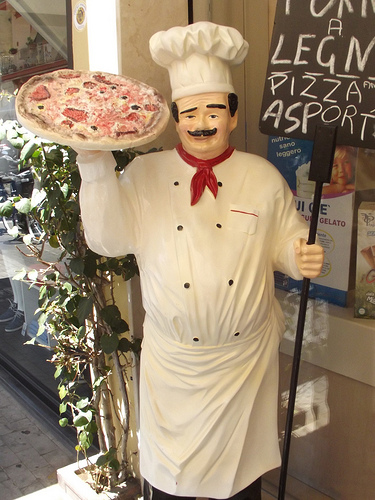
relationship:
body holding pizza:
[70, 19, 325, 499] [14, 69, 171, 152]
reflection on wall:
[283, 290, 332, 439] [0, 0, 373, 499]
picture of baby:
[268, 133, 354, 305] [320, 147, 356, 200]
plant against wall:
[0, 120, 133, 483] [0, 0, 373, 499]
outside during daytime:
[1, 0, 373, 499] [1, 1, 374, 500]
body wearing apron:
[70, 19, 325, 499] [138, 321, 282, 495]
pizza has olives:
[14, 69, 171, 152] [38, 104, 44, 109]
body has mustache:
[70, 19, 325, 499] [186, 128, 218, 137]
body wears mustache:
[70, 19, 325, 499] [186, 128, 218, 137]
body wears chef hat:
[70, 19, 325, 499] [150, 20, 249, 100]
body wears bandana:
[70, 19, 325, 499] [175, 144, 235, 206]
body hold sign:
[70, 19, 325, 499] [259, 0, 374, 499]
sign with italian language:
[259, 0, 374, 499] [259, 2, 374, 145]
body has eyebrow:
[70, 19, 325, 499] [178, 104, 226, 114]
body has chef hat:
[70, 19, 325, 499] [150, 20, 249, 100]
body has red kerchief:
[70, 19, 325, 499] [175, 144, 235, 206]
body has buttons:
[70, 19, 325, 499] [173, 181, 240, 342]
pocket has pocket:
[226, 205, 260, 236] [228, 207, 259, 219]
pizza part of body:
[14, 69, 171, 152] [70, 19, 325, 499]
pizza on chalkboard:
[270, 74, 363, 104] [258, 1, 374, 148]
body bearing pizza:
[70, 19, 325, 499] [14, 69, 171, 152]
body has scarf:
[70, 19, 325, 499] [175, 144, 235, 206]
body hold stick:
[70, 19, 325, 499] [277, 181, 325, 499]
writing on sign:
[259, 2, 374, 145] [259, 0, 374, 499]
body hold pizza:
[70, 19, 325, 499] [14, 69, 171, 152]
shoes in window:
[1, 301, 26, 335] [0, 0, 97, 413]